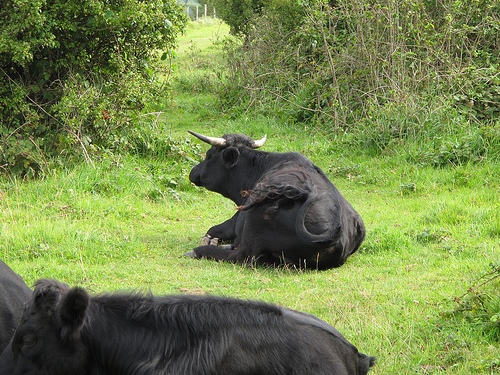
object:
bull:
[183, 129, 367, 271]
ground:
[2, 22, 499, 373]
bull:
[0, 278, 379, 375]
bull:
[1, 255, 32, 352]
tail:
[234, 164, 338, 244]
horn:
[187, 130, 226, 146]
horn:
[254, 133, 267, 147]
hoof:
[200, 233, 218, 246]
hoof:
[183, 250, 198, 259]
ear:
[221, 147, 241, 170]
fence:
[184, 4, 218, 21]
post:
[204, 4, 207, 17]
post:
[196, 4, 199, 20]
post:
[213, 5, 216, 18]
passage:
[141, 86, 230, 134]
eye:
[15, 333, 36, 349]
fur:
[234, 151, 366, 270]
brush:
[1, 0, 191, 181]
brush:
[203, 0, 500, 140]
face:
[189, 147, 220, 190]